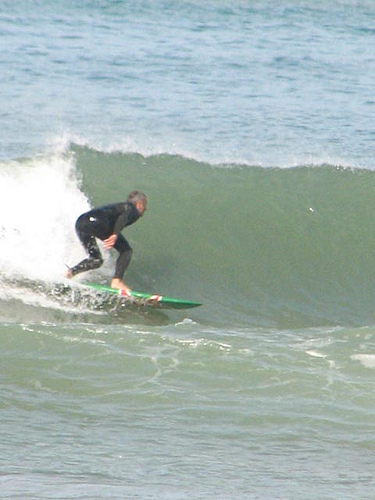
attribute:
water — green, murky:
[204, 157, 374, 329]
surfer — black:
[64, 190, 154, 295]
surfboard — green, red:
[8, 268, 205, 313]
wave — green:
[57, 134, 374, 326]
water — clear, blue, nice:
[1, 0, 370, 149]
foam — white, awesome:
[1, 138, 96, 267]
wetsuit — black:
[72, 198, 139, 277]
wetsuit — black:
[68, 200, 140, 281]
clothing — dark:
[72, 200, 140, 281]